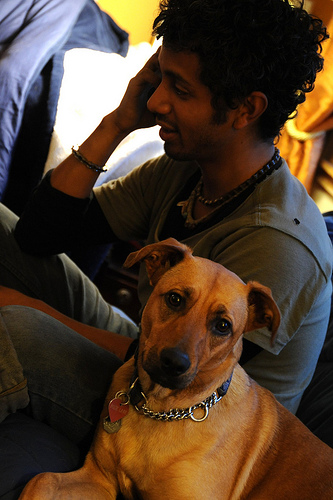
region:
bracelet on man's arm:
[66, 147, 116, 182]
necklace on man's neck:
[185, 147, 290, 218]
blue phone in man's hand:
[139, 60, 163, 106]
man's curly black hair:
[189, 1, 326, 85]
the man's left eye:
[171, 83, 192, 93]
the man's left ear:
[233, 86, 271, 149]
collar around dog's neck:
[120, 380, 247, 425]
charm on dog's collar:
[104, 392, 132, 436]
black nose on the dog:
[158, 346, 194, 376]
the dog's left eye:
[210, 309, 234, 340]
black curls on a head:
[209, 19, 281, 78]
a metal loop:
[188, 402, 209, 420]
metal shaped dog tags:
[102, 395, 123, 434]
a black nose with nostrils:
[156, 348, 192, 377]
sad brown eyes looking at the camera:
[166, 288, 239, 340]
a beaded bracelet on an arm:
[66, 141, 113, 180]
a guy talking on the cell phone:
[13, 1, 319, 412]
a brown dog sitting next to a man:
[68, 276, 314, 492]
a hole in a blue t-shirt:
[287, 209, 303, 226]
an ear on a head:
[228, 92, 271, 136]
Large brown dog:
[5, 230, 331, 498]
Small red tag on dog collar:
[92, 391, 133, 436]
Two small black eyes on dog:
[156, 278, 240, 349]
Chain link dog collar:
[122, 361, 252, 435]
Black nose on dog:
[155, 339, 194, 381]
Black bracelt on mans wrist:
[57, 142, 111, 176]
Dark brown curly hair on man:
[146, 0, 331, 165]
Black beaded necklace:
[168, 154, 293, 215]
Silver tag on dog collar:
[98, 413, 128, 438]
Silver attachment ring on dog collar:
[184, 397, 217, 429]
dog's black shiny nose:
[157, 345, 193, 373]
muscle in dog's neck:
[240, 443, 265, 473]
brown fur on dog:
[279, 443, 300, 468]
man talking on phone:
[84, 29, 270, 155]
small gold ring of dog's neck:
[180, 400, 211, 422]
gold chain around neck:
[119, 395, 224, 424]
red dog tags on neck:
[92, 391, 134, 430]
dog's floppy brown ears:
[127, 235, 289, 331]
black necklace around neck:
[163, 174, 269, 205]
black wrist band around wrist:
[67, 151, 113, 170]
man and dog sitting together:
[5, 1, 322, 498]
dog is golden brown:
[12, 238, 327, 495]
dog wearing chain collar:
[74, 343, 254, 441]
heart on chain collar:
[92, 374, 140, 429]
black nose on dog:
[136, 321, 210, 401]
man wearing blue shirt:
[100, 135, 331, 425]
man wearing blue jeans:
[0, 288, 140, 495]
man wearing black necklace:
[168, 137, 286, 223]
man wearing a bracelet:
[63, 134, 127, 184]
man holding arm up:
[25, 7, 240, 273]